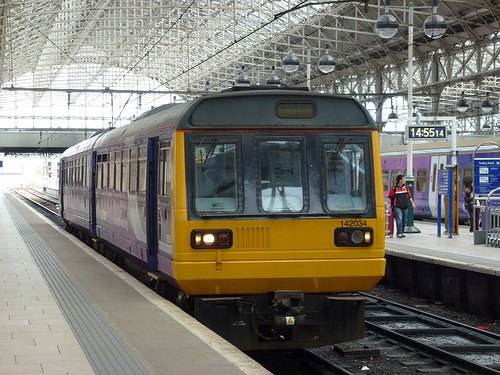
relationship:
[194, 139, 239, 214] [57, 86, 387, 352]
window of train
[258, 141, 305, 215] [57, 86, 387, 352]
window on train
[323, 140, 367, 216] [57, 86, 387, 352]
window in train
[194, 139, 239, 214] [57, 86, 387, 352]
window on train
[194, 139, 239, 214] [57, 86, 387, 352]
window on a train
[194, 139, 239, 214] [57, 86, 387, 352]
window in train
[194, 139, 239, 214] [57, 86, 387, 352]
window inside train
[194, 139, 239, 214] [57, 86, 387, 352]
window inside of train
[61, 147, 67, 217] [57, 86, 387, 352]
back of train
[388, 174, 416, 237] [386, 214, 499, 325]
person on top of platform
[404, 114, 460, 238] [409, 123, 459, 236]
clock on a post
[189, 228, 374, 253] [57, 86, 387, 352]
lights on train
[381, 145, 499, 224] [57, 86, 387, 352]
train opposite other train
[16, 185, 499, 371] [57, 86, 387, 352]
tracks for train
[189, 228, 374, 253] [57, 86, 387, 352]
lights are on train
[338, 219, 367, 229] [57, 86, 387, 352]
number written on train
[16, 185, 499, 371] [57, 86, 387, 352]
tracks carrying train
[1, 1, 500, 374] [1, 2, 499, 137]
train station with high ceiling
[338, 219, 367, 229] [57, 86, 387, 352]
number on train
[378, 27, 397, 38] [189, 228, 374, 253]
glass over lights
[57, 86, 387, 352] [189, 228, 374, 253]
train with lights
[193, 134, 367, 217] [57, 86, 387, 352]
windows on train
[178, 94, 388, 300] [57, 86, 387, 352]
front of train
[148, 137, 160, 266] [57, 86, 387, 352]
door inside train